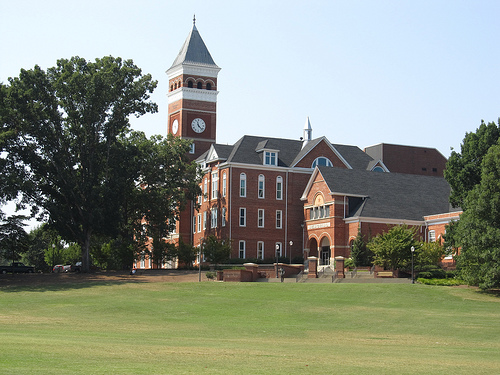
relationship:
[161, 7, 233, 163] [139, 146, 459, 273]
clock tower on church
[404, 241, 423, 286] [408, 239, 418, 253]
lamp post with white shade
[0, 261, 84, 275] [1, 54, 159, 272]
cars parked by tree